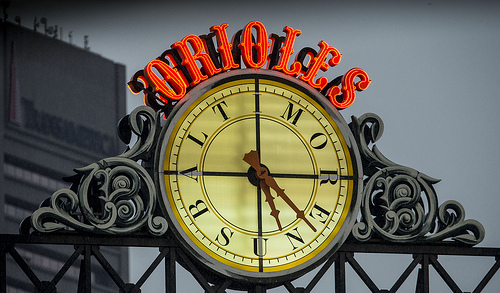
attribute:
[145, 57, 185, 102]
letter — orange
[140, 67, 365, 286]
clock — round, yellow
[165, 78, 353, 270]
face — yellow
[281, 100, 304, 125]
letter — m, black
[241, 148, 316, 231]
hand — rust red, minute, metal, brown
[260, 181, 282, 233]
hand — rust red, hour, metal, brown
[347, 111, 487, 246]
scrollwork — metal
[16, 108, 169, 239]
scrollwork — metal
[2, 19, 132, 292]
building — grey, tall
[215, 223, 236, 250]
letter — black, s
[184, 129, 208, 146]
letter — black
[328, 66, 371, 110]
letter — orange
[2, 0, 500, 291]
sky — dark, grey, overcast, cloudy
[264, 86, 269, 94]
tick — black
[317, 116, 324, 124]
tick — black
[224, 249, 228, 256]
tick — black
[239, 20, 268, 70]
letter — orange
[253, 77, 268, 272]
line — vertical, black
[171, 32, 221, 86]
letter — orange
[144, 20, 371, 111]
name — orioles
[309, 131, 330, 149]
letter — o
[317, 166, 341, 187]
letter — r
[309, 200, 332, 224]
letter — e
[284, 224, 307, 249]
letter — n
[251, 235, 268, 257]
letter — u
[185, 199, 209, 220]
letter — b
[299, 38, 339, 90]
letter — orange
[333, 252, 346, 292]
post — metal